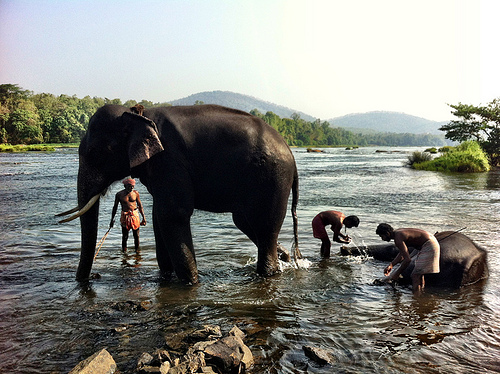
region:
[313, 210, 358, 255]
a person bent over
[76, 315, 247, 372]
rocks in the water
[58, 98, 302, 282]
a large elephant in the water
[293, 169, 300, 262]
the tail of the elephant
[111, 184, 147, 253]
a man holding a stick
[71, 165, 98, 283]
the trunk of the elephant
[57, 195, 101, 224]
the tusks of the elephant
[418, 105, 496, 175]
trees and grass in the background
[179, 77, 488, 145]
hills in the back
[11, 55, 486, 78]
the clear sky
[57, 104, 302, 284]
Elephant bathing with man in a river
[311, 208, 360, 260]
man bathing in river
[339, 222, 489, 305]
Man bathing elephant in river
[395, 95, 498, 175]
Trees along river bank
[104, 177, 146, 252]
Man wading in river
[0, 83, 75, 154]
Trees along the river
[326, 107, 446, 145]
Mountain in background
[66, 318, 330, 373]
Rocks in water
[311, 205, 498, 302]
Men bathing elephant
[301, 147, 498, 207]
River with rocks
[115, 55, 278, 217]
this is a large elephant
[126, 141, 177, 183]
the elephant is brown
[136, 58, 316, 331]
the elephant is dirty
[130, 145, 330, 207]
the elephant is black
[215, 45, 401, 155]
these are two mountains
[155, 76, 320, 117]
this is the highest peak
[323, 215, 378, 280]
this is a man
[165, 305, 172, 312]
these are some rocks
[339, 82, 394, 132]
there are no clouds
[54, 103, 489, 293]
Three men and two elephants in a river.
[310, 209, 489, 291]
The two men are washing the elephant.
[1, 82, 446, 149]
Trees line the riverbank.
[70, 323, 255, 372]
Large rocks in the water.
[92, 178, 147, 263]
A man standing with a stick in his hand.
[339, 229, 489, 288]
An elephant is lying in the water.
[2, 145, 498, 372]
A large and calm river.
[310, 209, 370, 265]
The man is splashing water on the elephant.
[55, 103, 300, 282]
A large elephant with tusks.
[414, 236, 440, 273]
The man has a piece of cloth wrapped around his waist.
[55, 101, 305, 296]
Large gray elephant standing in water.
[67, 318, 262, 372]
Rocks sticking out of water.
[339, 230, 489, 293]
Elephant laying down in water.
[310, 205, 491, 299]
Men bathing elephant in river.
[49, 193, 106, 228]
Long white tusks.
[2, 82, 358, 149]
Trees along the river.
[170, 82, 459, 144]
Mountains in the background.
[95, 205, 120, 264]
Stick in man's hand.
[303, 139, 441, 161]
Large rocks sticking out of river.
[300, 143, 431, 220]
Sun reflecting on water.